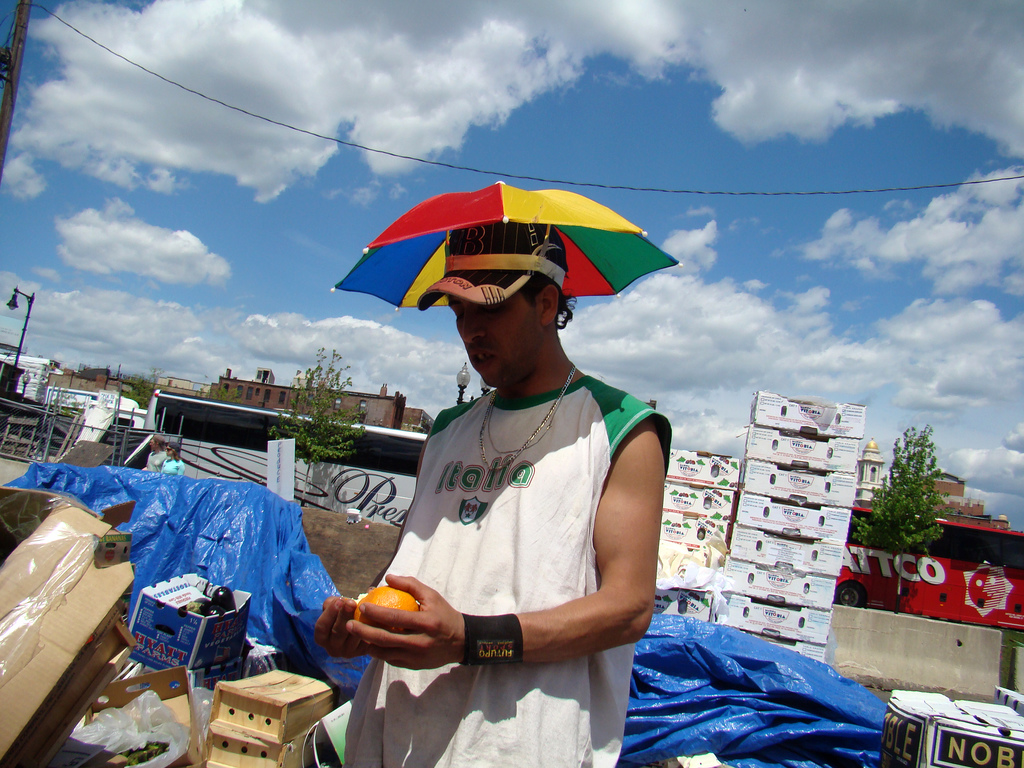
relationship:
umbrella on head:
[336, 169, 678, 299] [443, 219, 573, 386]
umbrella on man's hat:
[336, 169, 678, 299] [403, 195, 616, 347]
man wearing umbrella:
[318, 223, 675, 764] [336, 169, 678, 299]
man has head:
[318, 223, 675, 764] [443, 219, 573, 386]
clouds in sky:
[3, 1, 1023, 524] [7, 3, 1023, 529]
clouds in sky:
[52, 35, 366, 191] [32, 22, 1022, 256]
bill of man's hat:
[404, 258, 521, 319] [404, 195, 616, 347]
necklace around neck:
[505, 391, 575, 465] [510, 324, 586, 402]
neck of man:
[510, 324, 586, 402] [371, 225, 603, 452]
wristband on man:
[451, 605, 544, 675] [320, 188, 677, 722]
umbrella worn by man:
[335, 169, 677, 299] [455, 247, 559, 381]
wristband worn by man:
[451, 605, 544, 675] [384, 243, 659, 756]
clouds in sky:
[883, 325, 927, 377] [782, 240, 1020, 437]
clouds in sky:
[663, 273, 726, 340] [600, 199, 771, 366]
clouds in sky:
[671, 329, 756, 388] [645, 269, 764, 425]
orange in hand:
[358, 579, 413, 627] [350, 575, 472, 664]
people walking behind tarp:
[131, 426, 175, 470] [34, 463, 324, 522]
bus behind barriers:
[860, 508, 1020, 604] [842, 597, 1005, 708]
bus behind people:
[153, 385, 439, 515] [93, 404, 193, 482]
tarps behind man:
[49, 452, 909, 761] [399, 217, 648, 760]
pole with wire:
[4, 3, 31, 157] [31, 5, 991, 204]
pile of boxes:
[665, 390, 873, 661] [691, 446, 843, 594]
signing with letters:
[876, 707, 926, 759] [870, 705, 914, 745]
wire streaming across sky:
[31, 5, 991, 204] [260, 9, 930, 215]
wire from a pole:
[31, 5, 991, 204] [3, 7, 34, 116]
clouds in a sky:
[57, 9, 501, 178] [3, 1, 993, 384]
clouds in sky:
[49, 204, 235, 300] [462, 48, 959, 230]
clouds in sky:
[658, 249, 957, 381] [200, 178, 348, 285]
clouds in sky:
[675, 305, 961, 396] [550, 93, 730, 204]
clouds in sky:
[38, 3, 663, 151] [53, 9, 972, 360]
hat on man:
[327, 178, 684, 326] [318, 223, 676, 764]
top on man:
[336, 368, 667, 764] [318, 223, 676, 764]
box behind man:
[870, 665, 1022, 761] [318, 223, 676, 764]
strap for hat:
[423, 243, 598, 295] [328, 166, 674, 329]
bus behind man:
[860, 508, 1021, 604] [289, 168, 706, 765]